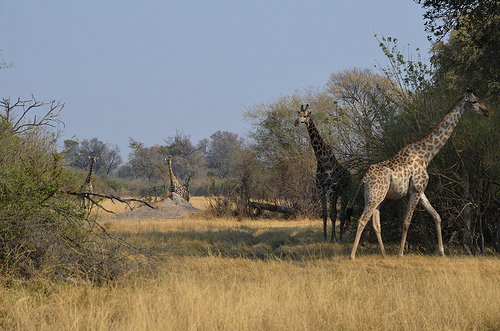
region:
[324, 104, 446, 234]
this is a giraffe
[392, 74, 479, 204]
the neck is long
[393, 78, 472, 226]
this is a neck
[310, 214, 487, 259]
these are two legs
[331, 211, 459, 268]
the legs are long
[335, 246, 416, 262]
these are two hooves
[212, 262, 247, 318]
the grass is long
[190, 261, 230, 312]
the grass is yellow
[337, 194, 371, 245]
this is a tail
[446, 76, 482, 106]
this is an eye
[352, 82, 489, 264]
Giraffe walking towards the right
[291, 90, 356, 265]
Giraffe walking to the left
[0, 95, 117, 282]
Green bush in the savannah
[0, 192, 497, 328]
Field with dead grass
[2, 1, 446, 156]
Sky without any clouds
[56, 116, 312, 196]
Multiple trees in the background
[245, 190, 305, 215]
Dead fallen tree lying on the ground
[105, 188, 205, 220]
Large rock in front of giraffe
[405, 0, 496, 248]
Large mountain behind giraffe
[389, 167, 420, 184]
Spots on side of giraffe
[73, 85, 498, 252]
the giraffes are four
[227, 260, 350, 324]
the grass is brown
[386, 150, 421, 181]
the spots are brown and white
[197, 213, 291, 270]
shadow is on the ground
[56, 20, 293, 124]
the sky has no clouds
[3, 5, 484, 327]
the animals are in africa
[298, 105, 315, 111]
the horns are short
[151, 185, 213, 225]
the ant hill is grey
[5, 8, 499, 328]
the scene was taken during the day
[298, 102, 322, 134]
the giraffe is looking at the camera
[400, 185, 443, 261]
The front legs of the giraffe on the right.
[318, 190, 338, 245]
The front legs of the giraffe on the left.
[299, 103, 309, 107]
The horns on the head of the giraffe on the left.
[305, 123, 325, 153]
The neck of the giraffe on the left.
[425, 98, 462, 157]
The neck of the giraffe on the right.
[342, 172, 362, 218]
The tail of the giraffe on the right.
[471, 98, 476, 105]
The eye of the giraffe on the right.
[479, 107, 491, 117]
The nose and mouth area of the giraffe on the right.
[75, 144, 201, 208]
The giraffes in the background.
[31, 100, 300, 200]
The trees in the background.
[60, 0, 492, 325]
Giraffes standing in the forest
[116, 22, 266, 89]
Blue sky with clouds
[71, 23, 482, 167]
Lot of trees in the forest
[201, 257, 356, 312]
Brown color grass in the forest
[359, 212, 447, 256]
Long legs of the forest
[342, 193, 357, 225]
Tail with fringes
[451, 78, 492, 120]
Head of the giraffe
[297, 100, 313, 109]
Short knobbed horns of the giraffe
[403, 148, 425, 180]
Brown polygons on a cream color backround of the giraffe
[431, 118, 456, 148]
Neck of the giraffe